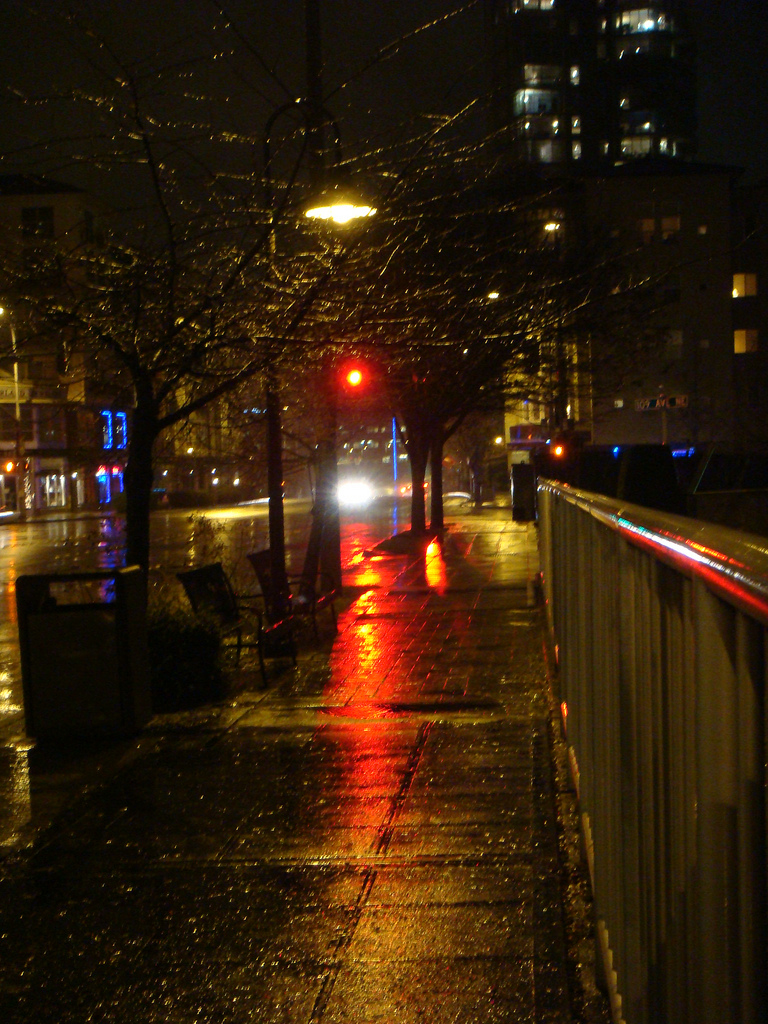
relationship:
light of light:
[347, 370, 362, 386] [347, 370, 362, 386]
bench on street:
[177, 562, 270, 688] [1, 445, 412, 715]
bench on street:
[177, 562, 270, 688] [0, 459, 434, 738]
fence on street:
[528, 476, 766, 1021] [0, 462, 454, 796]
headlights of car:
[336, 479, 375, 511] [385, 481, 419, 495]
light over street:
[347, 370, 362, 386] [0, 475, 452, 752]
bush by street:
[125, 591, 228, 721] [0, 462, 454, 796]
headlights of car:
[341, 479, 367, 496] [329, 470, 376, 505]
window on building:
[728, 325, 760, 360] [357, 0, 766, 535]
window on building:
[728, 325, 760, 360] [366, 7, 766, 472]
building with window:
[342, 0, 766, 492] [515, 0, 558, 12]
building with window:
[342, 0, 766, 492] [513, 88, 559, 114]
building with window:
[342, 0, 766, 492] [536, 204, 563, 244]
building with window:
[342, 0, 766, 492] [660, 212, 683, 238]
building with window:
[342, 0, 766, 492] [536, 135, 561, 160]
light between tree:
[345, 366, 360, 386] [389, 122, 490, 423]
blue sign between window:
[97, 471, 112, 506] [50, 421, 132, 507]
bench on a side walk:
[162, 526, 360, 718] [183, 601, 562, 1014]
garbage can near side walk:
[0, 552, 157, 761] [12, 684, 573, 982]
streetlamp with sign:
[0, 304, 37, 522] [0, 446, 50, 486]